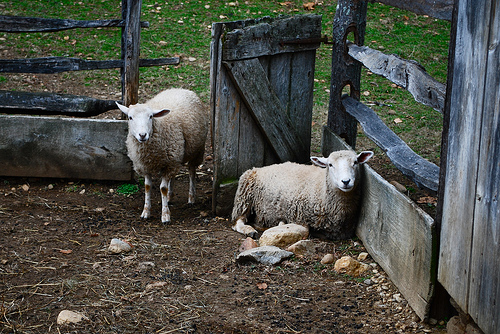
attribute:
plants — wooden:
[30, 182, 374, 323]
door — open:
[191, 7, 320, 201]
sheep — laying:
[103, 108, 373, 292]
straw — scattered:
[75, 267, 155, 314]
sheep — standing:
[129, 79, 199, 210]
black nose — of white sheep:
[342, 175, 351, 192]